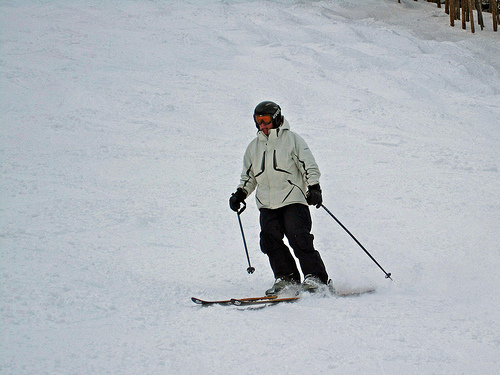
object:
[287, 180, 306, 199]
line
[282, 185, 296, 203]
line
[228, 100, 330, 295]
person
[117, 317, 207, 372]
snow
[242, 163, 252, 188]
line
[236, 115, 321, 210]
jacket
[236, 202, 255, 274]
ski pole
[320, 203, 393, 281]
pole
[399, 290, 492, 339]
snow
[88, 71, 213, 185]
snow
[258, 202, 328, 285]
black pants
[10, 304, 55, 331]
snow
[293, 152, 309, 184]
line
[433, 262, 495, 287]
snow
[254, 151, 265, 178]
line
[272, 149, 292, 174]
line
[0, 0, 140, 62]
snow